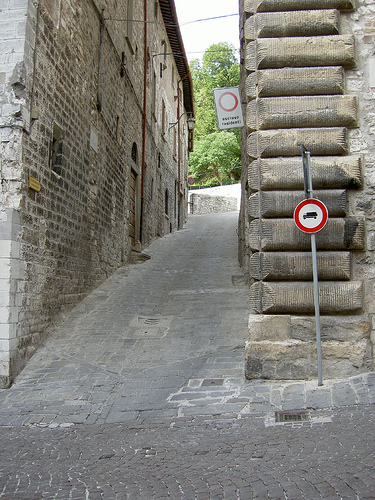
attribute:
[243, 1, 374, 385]
wall — stone, brick, wooden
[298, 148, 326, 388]
pole — long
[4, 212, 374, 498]
road — brick, alleyway, brick layered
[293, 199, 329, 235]
sign — round, dirty, red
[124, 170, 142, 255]
door — brown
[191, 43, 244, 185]
tree — green, long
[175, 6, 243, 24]
line — power line, electric cable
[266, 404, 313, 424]
drain — grill, red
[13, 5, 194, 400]
wall — stone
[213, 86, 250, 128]
sign — rectangular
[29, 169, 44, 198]
sign — yellow